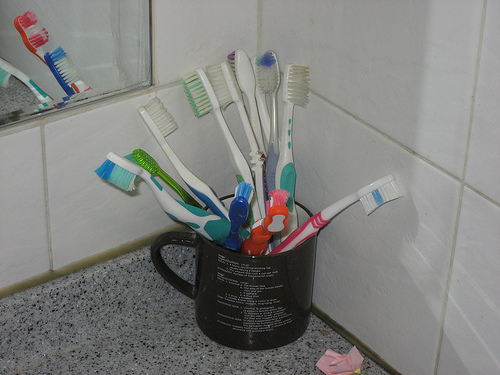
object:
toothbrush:
[137, 96, 232, 223]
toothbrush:
[205, 61, 266, 227]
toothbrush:
[227, 48, 266, 218]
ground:
[0, 300, 500, 375]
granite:
[0, 303, 164, 375]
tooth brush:
[93, 152, 251, 247]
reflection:
[0, 10, 94, 115]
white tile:
[331, 0, 500, 375]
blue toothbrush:
[221, 181, 254, 253]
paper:
[315, 346, 364, 375]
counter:
[1, 227, 385, 375]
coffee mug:
[150, 193, 318, 351]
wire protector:
[308, 340, 372, 370]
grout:
[4, 234, 145, 299]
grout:
[311, 301, 413, 373]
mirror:
[1, 0, 154, 139]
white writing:
[217, 254, 293, 332]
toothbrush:
[267, 173, 404, 255]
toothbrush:
[274, 63, 309, 248]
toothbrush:
[256, 50, 280, 255]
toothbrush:
[180, 67, 261, 228]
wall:
[0, 1, 500, 375]